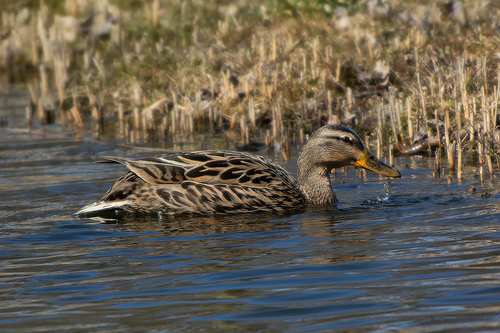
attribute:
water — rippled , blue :
[0, 85, 498, 331]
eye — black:
[342, 136, 350, 141]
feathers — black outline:
[74, 139, 338, 220]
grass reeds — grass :
[1, 0, 499, 201]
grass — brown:
[0, 0, 497, 179]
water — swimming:
[175, 244, 363, 331]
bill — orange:
[352, 152, 402, 182]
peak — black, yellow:
[355, 149, 402, 184]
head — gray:
[297, 122, 400, 178]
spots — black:
[187, 155, 272, 187]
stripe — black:
[322, 132, 342, 139]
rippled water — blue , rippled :
[158, 264, 295, 325]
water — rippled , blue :
[409, 245, 459, 285]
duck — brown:
[79, 121, 402, 229]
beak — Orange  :
[352, 149, 403, 182]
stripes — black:
[308, 124, 358, 154]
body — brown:
[72, 146, 313, 229]